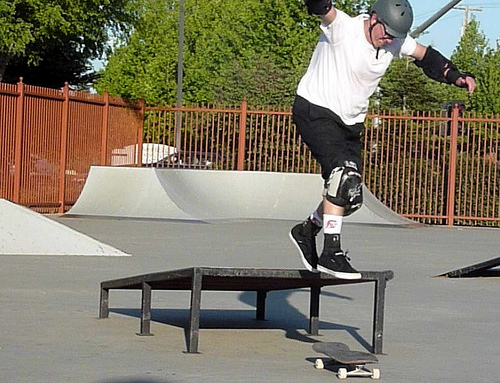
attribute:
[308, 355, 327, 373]
wheel — white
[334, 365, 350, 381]
wheel — white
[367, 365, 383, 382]
wheel — white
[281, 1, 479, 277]
man — skating, light skinned, jumping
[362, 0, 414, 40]
helmet — black, grey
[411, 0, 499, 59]
sky — blue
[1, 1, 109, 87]
tree — green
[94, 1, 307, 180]
tree — green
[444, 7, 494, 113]
tree — green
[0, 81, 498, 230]
fence — red, orange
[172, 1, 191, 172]
pole — grey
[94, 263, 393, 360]
ramp — metal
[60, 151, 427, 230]
ramp — concrete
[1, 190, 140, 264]
ramp — concrete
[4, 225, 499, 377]
floor — smooth, concrete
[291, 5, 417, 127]
shirt — white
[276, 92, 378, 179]
shorts — black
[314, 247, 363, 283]
shoes — black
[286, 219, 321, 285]
shoes — black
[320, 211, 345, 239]
socks — white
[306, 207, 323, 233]
socks — white